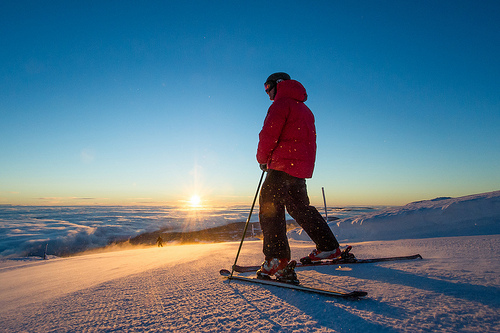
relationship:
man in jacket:
[250, 57, 358, 277] [255, 85, 326, 179]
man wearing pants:
[250, 57, 358, 277] [253, 166, 334, 262]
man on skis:
[250, 57, 358, 277] [211, 240, 444, 308]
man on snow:
[250, 57, 358, 277] [22, 238, 497, 330]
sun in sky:
[175, 194, 216, 219] [0, 0, 499, 211]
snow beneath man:
[22, 238, 497, 330] [250, 57, 358, 277]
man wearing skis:
[250, 57, 358, 277] [211, 240, 444, 308]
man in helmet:
[250, 57, 358, 277] [260, 69, 294, 84]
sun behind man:
[175, 194, 216, 219] [250, 57, 358, 277]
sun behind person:
[175, 194, 216, 219] [151, 232, 170, 253]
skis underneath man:
[211, 240, 444, 308] [250, 57, 358, 277]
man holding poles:
[250, 57, 358, 277] [207, 150, 287, 266]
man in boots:
[250, 57, 358, 277] [249, 236, 365, 287]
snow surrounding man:
[22, 238, 497, 330] [250, 57, 358, 277]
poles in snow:
[207, 150, 287, 266] [22, 238, 497, 330]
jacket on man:
[255, 85, 326, 179] [250, 57, 358, 277]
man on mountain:
[250, 57, 358, 277] [82, 214, 483, 323]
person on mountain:
[151, 232, 170, 253] [82, 214, 483, 323]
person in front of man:
[151, 232, 170, 253] [250, 57, 358, 277]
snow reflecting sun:
[22, 238, 497, 330] [175, 194, 216, 219]